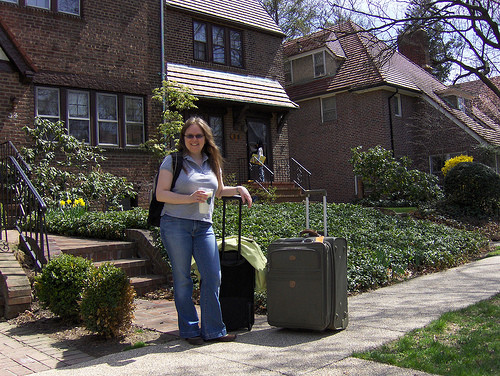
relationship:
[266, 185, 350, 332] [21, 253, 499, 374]
suitcase on sidewalk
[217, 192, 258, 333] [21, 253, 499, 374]
suitcase on sidewalk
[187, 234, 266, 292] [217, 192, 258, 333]
sweater on suitcase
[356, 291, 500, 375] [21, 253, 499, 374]
grass next to sidewalk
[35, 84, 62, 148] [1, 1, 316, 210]
window on house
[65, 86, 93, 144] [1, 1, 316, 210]
window on house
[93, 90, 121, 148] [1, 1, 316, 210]
window on house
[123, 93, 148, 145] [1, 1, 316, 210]
window on house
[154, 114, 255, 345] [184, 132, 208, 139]
girl wearing sunglasses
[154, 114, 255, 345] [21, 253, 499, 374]
girl standing on sidewalk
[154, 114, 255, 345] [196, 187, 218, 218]
girl holding mug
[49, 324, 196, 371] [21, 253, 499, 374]
shadow on sidewalk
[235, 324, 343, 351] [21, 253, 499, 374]
shadow on sidewalk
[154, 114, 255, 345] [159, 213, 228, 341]
girl wearing jeans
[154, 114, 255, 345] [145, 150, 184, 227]
girl carrying backpack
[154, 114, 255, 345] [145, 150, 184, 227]
girl has backpack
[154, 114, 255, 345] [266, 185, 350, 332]
girl has suitcase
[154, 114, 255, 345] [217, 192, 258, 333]
girl has suitcase